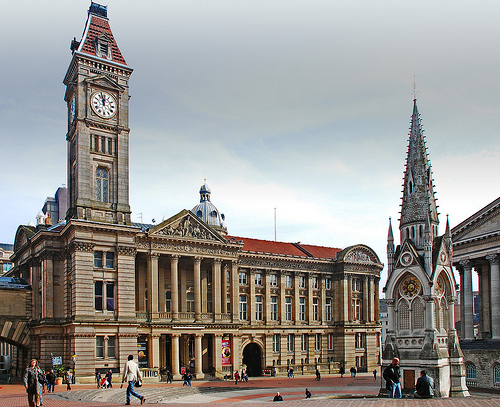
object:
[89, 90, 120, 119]
clock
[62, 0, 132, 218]
tower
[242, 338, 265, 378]
doorway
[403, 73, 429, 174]
steeple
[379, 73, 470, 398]
building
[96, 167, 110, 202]
windows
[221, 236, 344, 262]
roof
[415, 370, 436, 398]
man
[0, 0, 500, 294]
sky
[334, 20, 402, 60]
clouds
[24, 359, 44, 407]
people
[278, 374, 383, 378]
sidewalk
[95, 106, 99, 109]
numerals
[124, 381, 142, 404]
jeans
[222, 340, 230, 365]
banner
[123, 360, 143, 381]
top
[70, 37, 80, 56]
vent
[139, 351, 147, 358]
sign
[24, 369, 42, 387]
jacket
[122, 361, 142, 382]
coat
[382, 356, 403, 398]
person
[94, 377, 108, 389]
stroller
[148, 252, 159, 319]
columns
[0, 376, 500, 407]
street